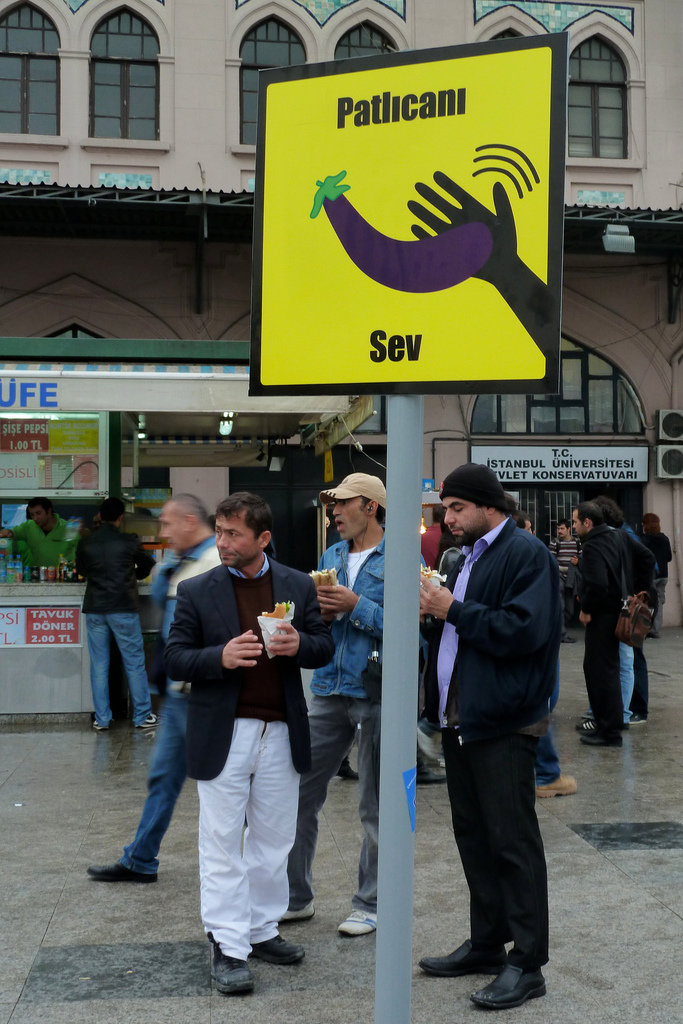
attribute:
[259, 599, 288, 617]
sandwich — large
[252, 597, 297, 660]
paper — white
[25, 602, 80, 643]
sign — small, square, red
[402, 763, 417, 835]
sign — small, rectangular, blue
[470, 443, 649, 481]
sign — big, black, white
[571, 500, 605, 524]
hair — dark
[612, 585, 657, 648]
bag — large, brown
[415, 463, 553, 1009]
man — black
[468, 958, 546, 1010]
shoe — black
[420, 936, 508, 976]
shoe — black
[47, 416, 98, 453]
sign — small, square, yellow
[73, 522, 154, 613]
jacket — black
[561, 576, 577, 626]
pants — black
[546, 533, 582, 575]
top — striped, long sleeve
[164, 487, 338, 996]
person — standing